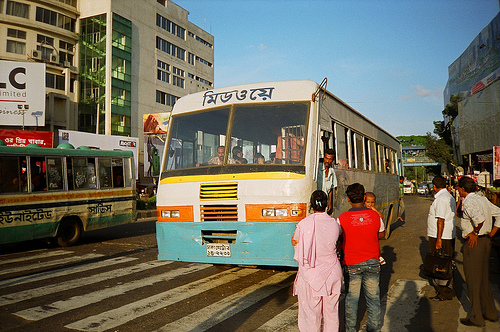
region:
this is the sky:
[236, 4, 397, 69]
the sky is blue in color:
[298, 15, 408, 56]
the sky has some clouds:
[401, 85, 436, 95]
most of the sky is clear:
[238, 14, 454, 46]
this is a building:
[98, 0, 138, 131]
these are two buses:
[6, 145, 226, 255]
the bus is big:
[182, 101, 268, 259]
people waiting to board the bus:
[307, 178, 477, 314]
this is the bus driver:
[205, 146, 231, 163]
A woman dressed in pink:
[294, 190, 341, 328]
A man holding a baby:
[341, 182, 393, 328]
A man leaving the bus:
[318, 127, 339, 189]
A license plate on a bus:
[206, 243, 231, 255]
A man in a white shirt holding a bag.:
[424, 175, 459, 312]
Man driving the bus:
[193, 142, 230, 167]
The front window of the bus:
[169, 104, 312, 170]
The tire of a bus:
[57, 215, 84, 245]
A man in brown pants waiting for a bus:
[456, 177, 499, 323]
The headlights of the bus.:
[158, 206, 291, 220]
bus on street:
[151, 75, 406, 265]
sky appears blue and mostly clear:
[206, 5, 447, 108]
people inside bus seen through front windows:
[171, 113, 296, 165]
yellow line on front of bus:
[155, 170, 301, 182]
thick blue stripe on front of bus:
[151, 220, 298, 263]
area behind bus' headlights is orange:
[152, 197, 308, 222]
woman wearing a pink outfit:
[285, 185, 340, 326]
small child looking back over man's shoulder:
[341, 180, 388, 236]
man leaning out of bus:
[305, 135, 340, 220]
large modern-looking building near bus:
[0, 0, 215, 207]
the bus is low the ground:
[156, 79, 403, 260]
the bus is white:
[153, 80, 403, 260]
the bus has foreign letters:
[201, 86, 271, 108]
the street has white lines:
[1, 247, 491, 328]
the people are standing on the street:
[294, 175, 499, 329]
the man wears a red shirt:
[338, 208, 380, 267]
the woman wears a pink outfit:
[292, 213, 335, 328]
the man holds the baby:
[365, 195, 377, 207]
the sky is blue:
[166, 0, 496, 137]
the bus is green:
[0, 145, 134, 242]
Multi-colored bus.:
[156, 84, 411, 269]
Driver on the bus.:
[196, 138, 243, 171]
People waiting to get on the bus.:
[294, 181, 497, 326]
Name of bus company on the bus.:
[233, 86, 277, 106]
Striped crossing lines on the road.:
[2, 242, 452, 327]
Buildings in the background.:
[2, 1, 219, 198]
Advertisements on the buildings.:
[0, 57, 54, 129]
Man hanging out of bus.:
[317, 147, 349, 209]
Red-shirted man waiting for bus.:
[335, 183, 396, 329]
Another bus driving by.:
[2, 136, 149, 246]